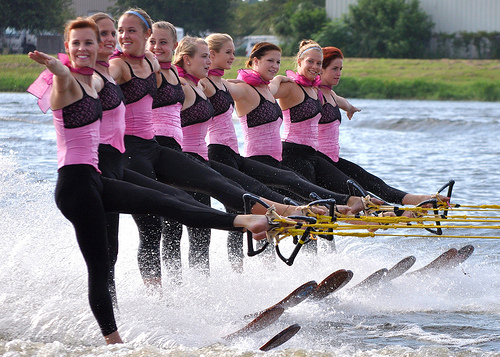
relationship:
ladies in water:
[25, 15, 455, 355] [24, 222, 498, 350]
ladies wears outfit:
[78, 10, 308, 317] [34, 78, 416, 228]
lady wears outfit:
[214, 40, 339, 252] [34, 78, 416, 228]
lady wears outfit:
[240, 46, 376, 215] [34, 78, 416, 228]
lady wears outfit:
[319, 47, 454, 207] [34, 78, 416, 228]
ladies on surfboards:
[25, 15, 455, 355] [208, 243, 478, 354]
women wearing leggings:
[34, 4, 479, 344] [52, 161, 240, 335]